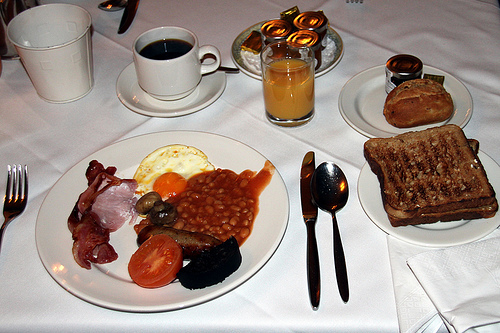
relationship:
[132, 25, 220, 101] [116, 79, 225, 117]
cup on white saucer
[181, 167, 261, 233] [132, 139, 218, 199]
beans next to eggs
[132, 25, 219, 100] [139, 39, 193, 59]
cup of coffee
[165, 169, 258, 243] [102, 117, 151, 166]
beans on white plate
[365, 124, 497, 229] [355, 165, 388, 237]
bread on saucer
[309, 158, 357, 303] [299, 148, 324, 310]
spoon next to knife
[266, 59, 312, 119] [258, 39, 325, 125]
juice has glass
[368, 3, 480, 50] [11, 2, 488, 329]
white cloth on table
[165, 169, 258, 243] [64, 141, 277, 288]
beans in soup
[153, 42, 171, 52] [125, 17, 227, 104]
coffee in cup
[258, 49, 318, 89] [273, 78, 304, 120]
glass with juice